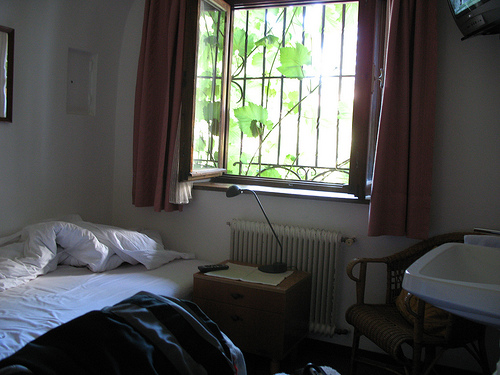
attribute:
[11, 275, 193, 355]
sheets — white 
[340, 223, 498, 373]
brown chair — wicker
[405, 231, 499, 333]
sink — white, porcelain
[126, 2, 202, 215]
curtains — brown 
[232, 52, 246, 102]
object — Black 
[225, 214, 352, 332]
radiator — white, steel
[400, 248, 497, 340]
sink — white 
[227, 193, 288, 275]
table lamp — metal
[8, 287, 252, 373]
blanket — blue 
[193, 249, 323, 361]
table — brown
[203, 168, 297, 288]
lamp — Black 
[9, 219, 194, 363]
sheet — white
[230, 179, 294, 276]
object — black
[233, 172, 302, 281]
object — black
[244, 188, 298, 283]
object — black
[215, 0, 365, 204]
bars — black, metal